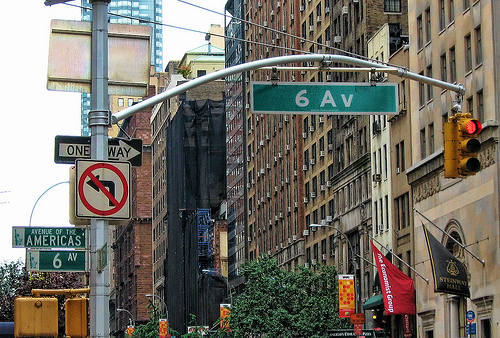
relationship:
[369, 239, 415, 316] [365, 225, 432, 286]
flag hanging from pole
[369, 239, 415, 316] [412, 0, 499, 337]
flag hanging from building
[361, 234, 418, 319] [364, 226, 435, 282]
flag hanging from pole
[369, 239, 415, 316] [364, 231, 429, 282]
flag hanging from pole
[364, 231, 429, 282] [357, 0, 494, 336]
pole hanging from building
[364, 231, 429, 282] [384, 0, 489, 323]
pole hanging from building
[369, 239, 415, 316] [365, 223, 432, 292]
flag on pole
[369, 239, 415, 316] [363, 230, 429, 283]
flag on pole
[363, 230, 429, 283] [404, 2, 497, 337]
pole on building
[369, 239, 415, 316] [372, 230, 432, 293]
flag on pole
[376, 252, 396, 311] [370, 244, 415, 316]
white lettering on red flag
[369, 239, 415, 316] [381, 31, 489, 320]
flag on building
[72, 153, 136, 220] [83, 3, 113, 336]
sign in pole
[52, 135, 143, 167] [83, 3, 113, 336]
black sign in pole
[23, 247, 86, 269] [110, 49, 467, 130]
sign in pole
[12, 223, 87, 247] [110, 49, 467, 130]
sign in pole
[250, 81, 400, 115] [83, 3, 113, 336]
sign in pole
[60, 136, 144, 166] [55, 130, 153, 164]
arrow in sign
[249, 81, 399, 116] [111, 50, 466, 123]
sign on pole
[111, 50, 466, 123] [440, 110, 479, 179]
pole with traffic light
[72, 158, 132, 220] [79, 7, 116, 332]
sign on pole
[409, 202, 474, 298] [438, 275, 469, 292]
flag with lettering